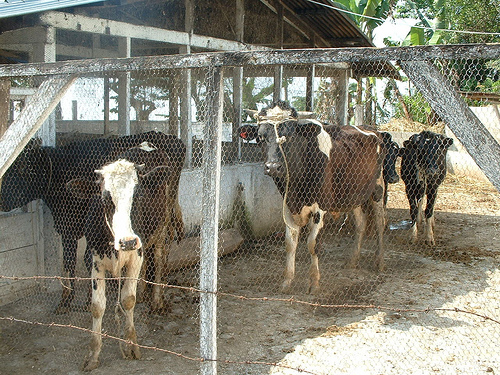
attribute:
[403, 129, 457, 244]
cow — white, black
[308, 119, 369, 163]
spot — white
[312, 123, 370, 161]
spot — white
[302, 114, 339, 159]
spot — white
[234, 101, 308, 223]
rope — white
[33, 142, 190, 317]
cow — brown, white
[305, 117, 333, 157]
spot — white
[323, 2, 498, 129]
trees — green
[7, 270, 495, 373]
wire — barbed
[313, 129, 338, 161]
spot — white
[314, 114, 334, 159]
spot — white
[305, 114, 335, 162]
spot — white